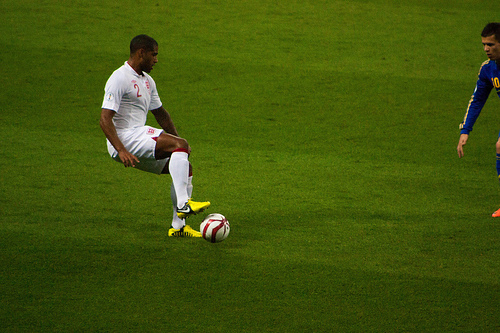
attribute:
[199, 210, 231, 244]
soccer ball — round, red, white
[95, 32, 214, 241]
man — playing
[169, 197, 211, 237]
shoes — bright, yellow, light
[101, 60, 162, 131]
jersey — white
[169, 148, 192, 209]
sock — white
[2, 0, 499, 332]
grass — thick, green, dark, bright, large, light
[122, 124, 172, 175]
shorts — white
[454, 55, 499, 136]
shirt — blue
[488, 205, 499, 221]
cleat — orange